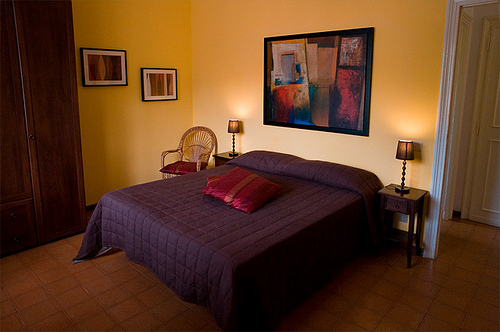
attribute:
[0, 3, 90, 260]
cabinet — tall, brown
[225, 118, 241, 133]
shade — brown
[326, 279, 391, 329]
tile — brown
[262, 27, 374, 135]
frame — large, black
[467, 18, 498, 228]
door — white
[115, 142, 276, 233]
purple bedspread — dark purple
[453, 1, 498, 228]
door — white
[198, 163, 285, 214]
pillow — red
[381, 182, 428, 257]
table — brown, tall, square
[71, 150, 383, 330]
bedspread — purple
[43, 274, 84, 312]
tile — BROWN 